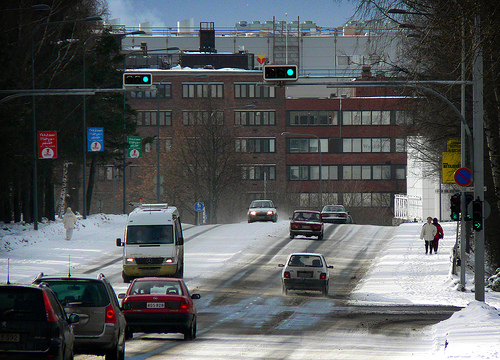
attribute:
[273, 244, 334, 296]
vehicle — white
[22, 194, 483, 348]
street — snowy 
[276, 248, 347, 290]
car — white, red 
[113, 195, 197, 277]
van — grey , large, white, yellow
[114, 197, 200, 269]
truck — white commercial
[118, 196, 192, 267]
van — white , yellow 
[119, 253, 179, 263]
van's headlights — on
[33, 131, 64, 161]
sign — red, white, rectangular, blue, green, round, yellow, black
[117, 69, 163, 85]
traffic light — green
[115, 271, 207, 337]
car — red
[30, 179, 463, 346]
city street — Slippery 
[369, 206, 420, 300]
fallen snow — fresh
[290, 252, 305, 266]
driver — small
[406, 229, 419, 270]
white lines — dashed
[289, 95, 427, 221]
building — red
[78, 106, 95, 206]
pole — metal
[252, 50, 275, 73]
flag — red, white, blue, green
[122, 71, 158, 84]
light — green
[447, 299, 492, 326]
snow — spiled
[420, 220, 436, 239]
coat — white, red